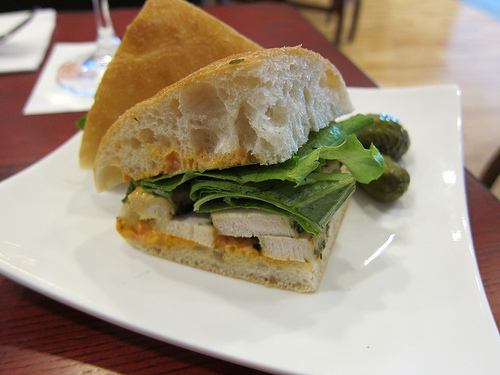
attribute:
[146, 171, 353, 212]
leaf — green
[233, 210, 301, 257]
meat — white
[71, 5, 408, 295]
sandwich — cut , half , chicken sandwich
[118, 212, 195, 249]
sauce — yellow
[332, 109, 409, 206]
pickles — green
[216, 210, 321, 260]
chicken — moist, white meat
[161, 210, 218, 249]
chicken — white meat, moist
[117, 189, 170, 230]
chicken — white meat, moist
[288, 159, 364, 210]
leaf — green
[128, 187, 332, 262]
chicken — white meat, moist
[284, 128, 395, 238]
leaf — green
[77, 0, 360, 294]
sandwich — chicken sandwich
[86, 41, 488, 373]
plate — flat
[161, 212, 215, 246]
chicken — moist, white meat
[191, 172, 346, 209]
leaf — green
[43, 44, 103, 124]
napkin — white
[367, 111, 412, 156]
caper — sour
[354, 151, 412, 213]
caper — dark green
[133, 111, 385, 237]
lettuce topping — green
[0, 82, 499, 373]
plate — small, square, white, geometrically shaped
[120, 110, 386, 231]
leaf — green